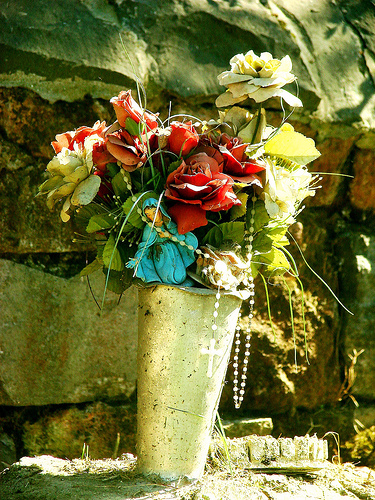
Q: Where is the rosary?
A: In the flowers.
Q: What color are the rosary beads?
A: White.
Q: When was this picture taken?
A: During the day.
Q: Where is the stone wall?
A: Behind the vase.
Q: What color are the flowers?
A: Red and white.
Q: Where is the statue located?
A: In the vase.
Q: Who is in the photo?
A: No one.